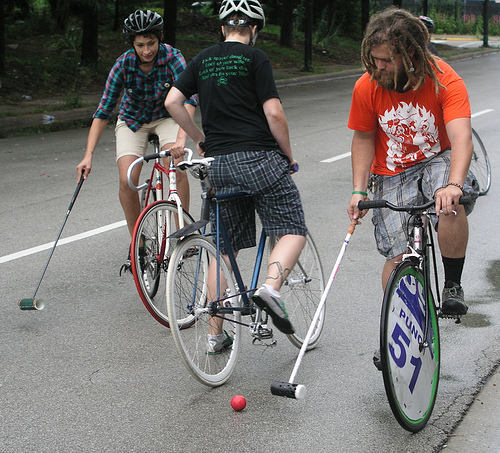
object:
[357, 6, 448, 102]
hair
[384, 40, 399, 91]
dreadlocks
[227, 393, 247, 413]
ball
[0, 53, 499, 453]
pavement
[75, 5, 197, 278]
woman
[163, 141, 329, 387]
bike